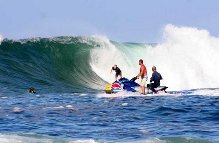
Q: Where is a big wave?
A: In the ocean.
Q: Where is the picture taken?
A: The ocean.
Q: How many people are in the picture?
A: 4.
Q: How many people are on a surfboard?
A: One.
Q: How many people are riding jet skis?
A: Two.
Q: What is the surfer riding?
A: A wave.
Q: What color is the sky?
A: Blue.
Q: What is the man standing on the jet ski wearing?
A: Shorts.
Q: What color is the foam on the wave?
A: White.